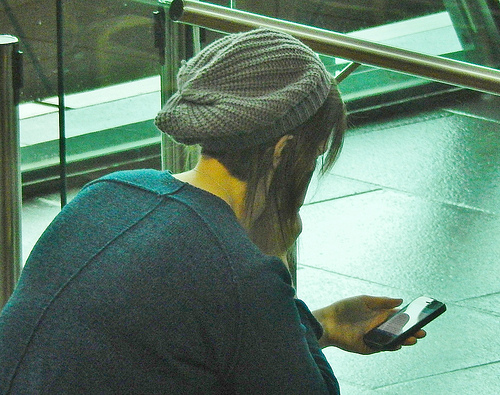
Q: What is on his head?
A: A tobogan.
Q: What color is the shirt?
A: Blue.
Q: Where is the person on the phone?
A: Sitting in a chair.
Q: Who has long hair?
A: The man.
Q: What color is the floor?
A: Gray.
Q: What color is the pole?
A: Silver.